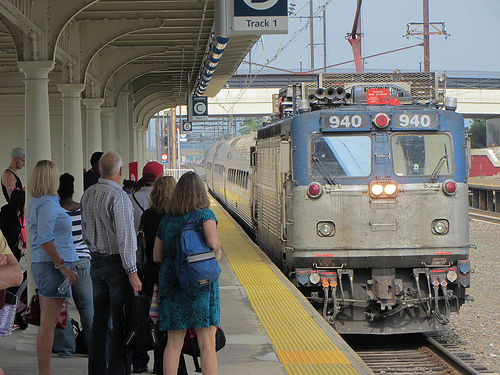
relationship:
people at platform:
[13, 122, 226, 350] [179, 163, 300, 349]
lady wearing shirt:
[21, 158, 89, 312] [24, 193, 77, 263]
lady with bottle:
[21, 158, 89, 312] [53, 271, 78, 297]